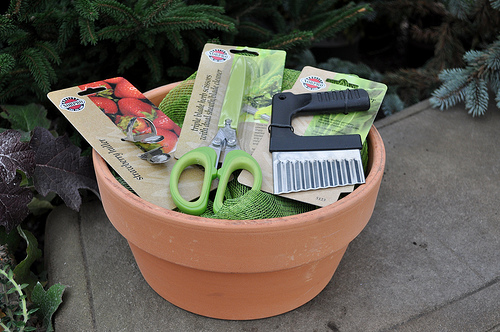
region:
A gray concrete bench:
[400, 219, 460, 291]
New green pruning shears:
[177, 49, 262, 219]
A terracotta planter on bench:
[144, 215, 274, 327]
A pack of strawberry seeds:
[62, 88, 170, 184]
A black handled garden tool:
[272, 85, 364, 204]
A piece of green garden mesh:
[232, 197, 284, 222]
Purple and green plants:
[6, 120, 80, 325]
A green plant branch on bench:
[425, 49, 494, 126]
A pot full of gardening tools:
[60, 37, 385, 304]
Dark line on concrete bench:
[64, 225, 93, 287]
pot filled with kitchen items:
[105, 17, 379, 315]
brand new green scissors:
[172, 49, 262, 213]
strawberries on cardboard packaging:
[107, 82, 144, 119]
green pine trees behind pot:
[14, 4, 194, 72]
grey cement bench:
[393, 125, 498, 320]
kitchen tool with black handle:
[263, 63, 381, 205]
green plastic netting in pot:
[231, 186, 310, 223]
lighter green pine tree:
[418, 23, 499, 119]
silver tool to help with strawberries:
[127, 100, 171, 179]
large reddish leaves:
[1, 114, 72, 229]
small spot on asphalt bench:
[406, 226, 454, 254]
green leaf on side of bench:
[20, 264, 79, 322]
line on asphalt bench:
[428, 274, 498, 310]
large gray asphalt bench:
[28, 151, 493, 301]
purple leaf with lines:
[10, 122, 100, 235]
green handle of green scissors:
[161, 140, 244, 237]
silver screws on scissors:
[209, 119, 253, 157]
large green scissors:
[171, 37, 276, 215]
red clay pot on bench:
[60, 91, 403, 329]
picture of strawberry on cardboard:
[94, 82, 149, 128]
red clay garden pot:
[63, 68, 403, 316]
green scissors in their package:
[171, 58, 266, 213]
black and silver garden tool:
[268, 87, 370, 199]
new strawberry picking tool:
[62, 78, 174, 208]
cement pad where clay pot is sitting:
[40, 88, 498, 327]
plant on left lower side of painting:
[1, 123, 87, 329]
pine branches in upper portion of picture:
[8, 3, 494, 113]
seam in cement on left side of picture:
[68, 199, 114, 329]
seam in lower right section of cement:
[383, 258, 498, 329]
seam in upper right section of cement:
[377, 81, 435, 133]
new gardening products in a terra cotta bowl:
[44, 39, 401, 296]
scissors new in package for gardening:
[158, 38, 264, 218]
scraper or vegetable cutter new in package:
[240, 51, 369, 194]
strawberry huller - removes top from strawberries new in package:
[41, 66, 193, 226]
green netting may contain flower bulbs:
[211, 186, 299, 224]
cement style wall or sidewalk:
[380, 97, 475, 298]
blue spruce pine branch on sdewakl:
[402, 6, 494, 146]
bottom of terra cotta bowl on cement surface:
[70, 236, 462, 325]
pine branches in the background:
[24, 6, 166, 63]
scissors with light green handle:
[175, 56, 263, 208]